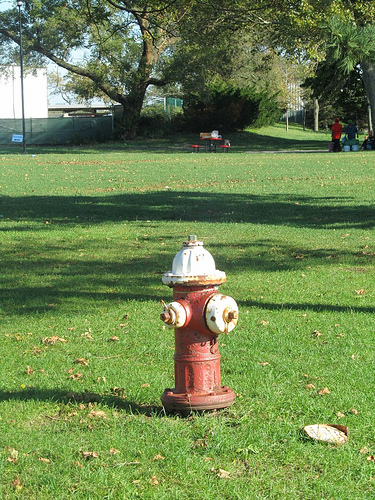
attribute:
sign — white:
[11, 133, 25, 143]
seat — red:
[188, 143, 200, 147]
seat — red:
[218, 144, 230, 149]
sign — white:
[8, 124, 27, 151]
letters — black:
[10, 130, 22, 138]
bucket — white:
[342, 144, 351, 152]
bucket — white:
[351, 143, 359, 151]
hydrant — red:
[140, 237, 247, 410]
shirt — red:
[332, 122, 343, 140]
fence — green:
[18, 107, 97, 143]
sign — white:
[3, 129, 25, 145]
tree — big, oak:
[2, 2, 252, 144]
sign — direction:
[9, 132, 23, 141]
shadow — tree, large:
[2, 188, 363, 326]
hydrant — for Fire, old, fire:
[160, 233, 240, 415]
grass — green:
[2, 126, 357, 498]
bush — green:
[164, 79, 281, 142]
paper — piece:
[302, 420, 353, 445]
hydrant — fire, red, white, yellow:
[155, 232, 236, 416]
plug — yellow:
[204, 291, 242, 340]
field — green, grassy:
[4, 133, 363, 496]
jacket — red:
[330, 123, 342, 140]